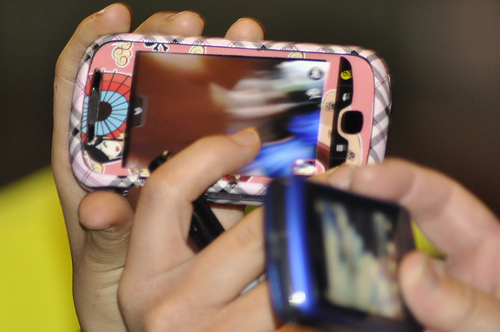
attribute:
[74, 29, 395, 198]
trim — plaid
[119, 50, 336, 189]
picture — blurry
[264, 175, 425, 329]
camera — black and blue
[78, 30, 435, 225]
phone — multicolored 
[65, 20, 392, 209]
cell phone — colored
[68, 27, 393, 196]
cellphone — pink and black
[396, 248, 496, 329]
finger — small, brown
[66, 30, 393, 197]
cell phone — colored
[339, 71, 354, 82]
button — yellow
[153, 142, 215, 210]
finger — brown, small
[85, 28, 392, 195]
mobile phone — colored 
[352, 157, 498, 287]
finger — brown 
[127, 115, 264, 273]
finger — brown 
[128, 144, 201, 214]
finger — brown, small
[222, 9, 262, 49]
finger — brown 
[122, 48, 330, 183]
screen — coloured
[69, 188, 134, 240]
finger — small, brown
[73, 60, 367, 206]
picture — blue orange red & black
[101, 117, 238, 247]
finger — brown 